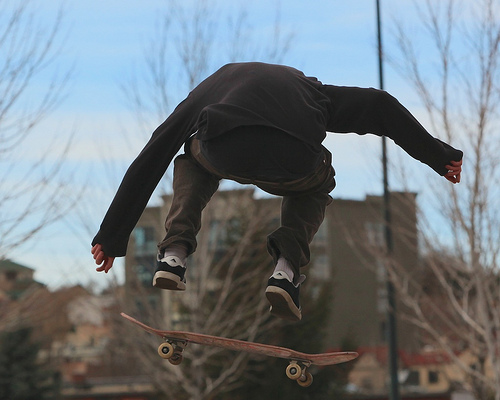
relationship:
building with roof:
[339, 317, 493, 390] [337, 322, 464, 370]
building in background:
[339, 317, 493, 390] [29, 141, 96, 262]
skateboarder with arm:
[126, 28, 471, 289] [331, 62, 437, 160]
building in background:
[114, 183, 432, 377] [29, 141, 96, 262]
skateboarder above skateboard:
[126, 28, 471, 289] [113, 290, 362, 390]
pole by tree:
[360, 11, 408, 239] [404, 15, 492, 201]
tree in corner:
[404, 15, 492, 201] [9, 8, 61, 367]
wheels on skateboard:
[153, 354, 306, 396] [113, 290, 362, 390]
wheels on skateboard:
[279, 345, 337, 389] [113, 290, 362, 390]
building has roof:
[339, 317, 493, 390] [337, 322, 464, 370]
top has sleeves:
[178, 54, 414, 169] [96, 59, 211, 220]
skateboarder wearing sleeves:
[126, 28, 471, 289] [96, 59, 211, 220]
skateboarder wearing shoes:
[126, 28, 471, 289] [138, 236, 299, 328]